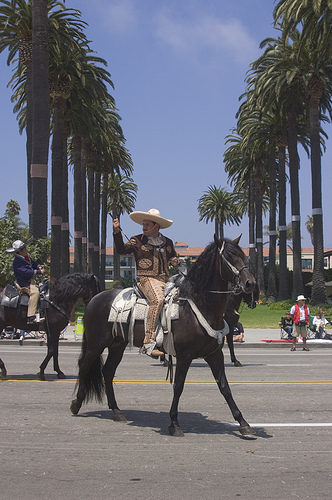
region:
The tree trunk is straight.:
[98, 163, 115, 300]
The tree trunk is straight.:
[90, 169, 101, 300]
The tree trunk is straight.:
[85, 158, 96, 280]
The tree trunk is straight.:
[71, 134, 83, 277]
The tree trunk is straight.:
[59, 130, 70, 282]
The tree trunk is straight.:
[28, 0, 47, 282]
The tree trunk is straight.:
[301, 88, 329, 309]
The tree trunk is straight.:
[284, 99, 308, 301]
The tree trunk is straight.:
[275, 132, 290, 307]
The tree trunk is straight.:
[253, 147, 268, 309]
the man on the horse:
[112, 208, 180, 356]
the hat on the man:
[129, 208, 172, 229]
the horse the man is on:
[70, 234, 256, 435]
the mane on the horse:
[177, 237, 243, 306]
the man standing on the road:
[289, 294, 308, 350]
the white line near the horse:
[225, 422, 331, 425]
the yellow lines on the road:
[0, 375, 331, 384]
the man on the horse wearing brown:
[111, 208, 179, 355]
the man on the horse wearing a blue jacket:
[6, 240, 44, 322]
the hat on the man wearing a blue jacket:
[4, 239, 29, 252]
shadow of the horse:
[70, 394, 273, 448]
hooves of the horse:
[166, 418, 249, 434]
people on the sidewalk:
[265, 278, 327, 354]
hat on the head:
[135, 205, 171, 225]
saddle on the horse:
[96, 291, 169, 340]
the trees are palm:
[26, 10, 101, 270]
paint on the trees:
[271, 210, 319, 228]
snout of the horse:
[240, 267, 255, 296]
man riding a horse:
[66, 188, 276, 451]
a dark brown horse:
[72, 232, 267, 442]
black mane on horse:
[176, 237, 239, 325]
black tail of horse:
[70, 278, 113, 418]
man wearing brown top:
[122, 223, 177, 278]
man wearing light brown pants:
[133, 274, 172, 344]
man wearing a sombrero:
[131, 206, 176, 230]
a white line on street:
[217, 405, 326, 451]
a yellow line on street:
[21, 360, 323, 402]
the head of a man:
[121, 199, 173, 251]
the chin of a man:
[131, 227, 160, 248]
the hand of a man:
[109, 213, 124, 234]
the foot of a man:
[136, 337, 171, 364]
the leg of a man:
[120, 277, 182, 369]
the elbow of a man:
[101, 232, 140, 273]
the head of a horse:
[200, 224, 268, 303]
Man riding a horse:
[67, 206, 258, 437]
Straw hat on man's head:
[127, 206, 171, 225]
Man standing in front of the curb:
[288, 291, 308, 351]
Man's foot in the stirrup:
[141, 324, 165, 357]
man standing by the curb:
[290, 293, 312, 352]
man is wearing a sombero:
[128, 201, 175, 236]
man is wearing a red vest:
[292, 302, 310, 324]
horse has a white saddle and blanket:
[109, 271, 229, 343]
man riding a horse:
[70, 209, 259, 441]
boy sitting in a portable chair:
[279, 311, 296, 339]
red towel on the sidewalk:
[260, 337, 300, 344]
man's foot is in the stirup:
[137, 331, 167, 356]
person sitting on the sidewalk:
[225, 314, 245, 343]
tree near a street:
[265, 8, 331, 54]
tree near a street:
[235, 76, 275, 109]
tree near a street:
[217, 134, 251, 168]